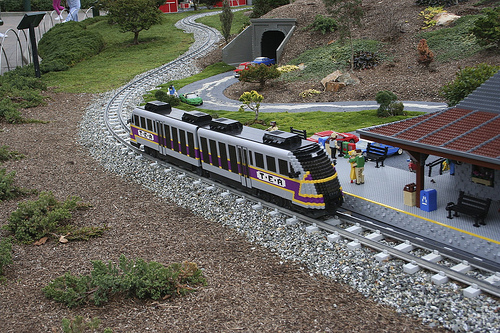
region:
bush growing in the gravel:
[41, 258, 221, 309]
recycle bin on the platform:
[421, 190, 436, 208]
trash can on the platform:
[401, 180, 418, 207]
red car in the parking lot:
[307, 119, 358, 149]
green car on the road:
[183, 83, 205, 107]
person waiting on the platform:
[336, 137, 376, 181]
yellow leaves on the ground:
[31, 233, 97, 253]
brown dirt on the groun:
[195, 228, 269, 284]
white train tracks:
[356, 215, 471, 284]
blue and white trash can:
[420, 185, 447, 210]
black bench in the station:
[448, 188, 493, 224]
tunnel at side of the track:
[227, 10, 314, 70]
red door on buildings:
[153, 1, 188, 13]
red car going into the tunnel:
[231, 54, 265, 82]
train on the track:
[119, 93, 361, 229]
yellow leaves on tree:
[236, 83, 285, 105]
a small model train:
[122, 83, 355, 236]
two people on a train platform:
[344, 138, 374, 198]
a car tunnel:
[207, 0, 312, 85]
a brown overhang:
[348, 85, 498, 193]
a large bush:
[10, 10, 110, 105]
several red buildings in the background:
[159, 0, 264, 22]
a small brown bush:
[405, 33, 445, 70]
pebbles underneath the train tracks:
[72, 5, 495, 331]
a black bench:
[361, 133, 395, 168]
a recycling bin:
[418, 179, 443, 223]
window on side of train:
[132, 114, 139, 126]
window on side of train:
[137, 115, 147, 129]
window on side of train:
[144, 118, 154, 130]